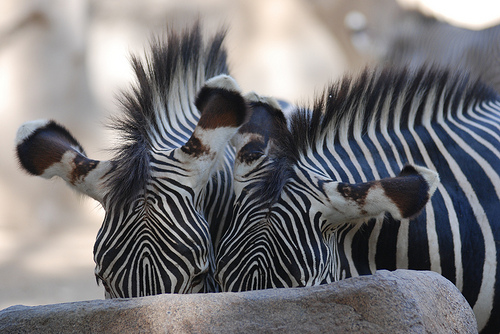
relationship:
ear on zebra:
[15, 113, 115, 198] [212, 52, 499, 332]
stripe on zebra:
[396, 104, 459, 298] [20, 28, 296, 306]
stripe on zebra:
[432, 89, 482, 317] [212, 52, 499, 332]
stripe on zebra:
[166, 183, 190, 250] [239, 63, 491, 298]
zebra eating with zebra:
[212, 52, 499, 332] [13, 0, 244, 308]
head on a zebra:
[204, 122, 442, 307] [212, 75, 496, 328]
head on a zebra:
[12, 68, 254, 294] [20, 28, 296, 306]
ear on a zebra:
[324, 157, 421, 237] [212, 75, 496, 328]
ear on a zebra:
[231, 86, 291, 189] [212, 75, 496, 328]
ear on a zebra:
[177, 84, 242, 171] [20, 28, 296, 306]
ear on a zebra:
[15, 113, 115, 198] [20, 28, 296, 306]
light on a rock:
[138, 291, 243, 333] [4, 271, 484, 329]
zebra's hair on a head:
[106, 124, 178, 213] [204, 122, 442, 307]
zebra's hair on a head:
[298, 62, 496, 147] [12, 68, 254, 294]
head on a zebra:
[204, 122, 442, 307] [8, 20, 325, 298]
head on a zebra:
[12, 68, 254, 294] [212, 52, 499, 332]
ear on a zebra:
[15, 113, 115, 198] [81, 112, 220, 289]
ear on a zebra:
[177, 74, 242, 170] [81, 112, 220, 289]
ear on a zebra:
[177, 74, 242, 170] [212, 52, 499, 332]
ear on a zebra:
[324, 157, 421, 237] [212, 52, 499, 332]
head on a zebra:
[204, 122, 442, 307] [212, 52, 499, 332]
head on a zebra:
[12, 68, 254, 205] [15, 13, 304, 309]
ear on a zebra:
[177, 74, 242, 170] [15, 13, 304, 309]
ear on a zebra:
[15, 113, 115, 198] [15, 13, 304, 309]